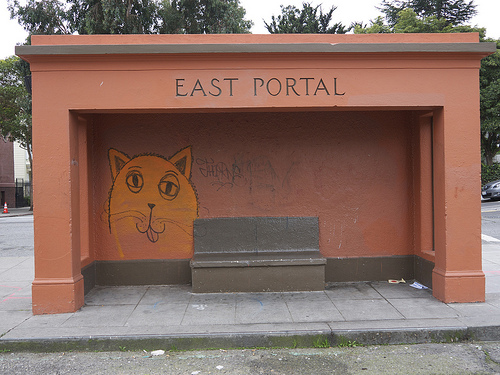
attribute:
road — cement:
[2, 335, 499, 372]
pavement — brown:
[0, 218, 498, 340]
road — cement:
[1, 340, 499, 373]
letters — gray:
[149, 69, 241, 110]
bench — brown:
[165, 210, 352, 297]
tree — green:
[13, 0, 248, 32]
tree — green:
[257, 0, 345, 30]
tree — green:
[380, 1, 482, 31]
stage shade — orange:
[30, 32, 485, 314]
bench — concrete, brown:
[187, 213, 332, 293]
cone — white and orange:
[173, 146, 198, 175]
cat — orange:
[107, 140, 205, 266]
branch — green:
[0, 41, 45, 158]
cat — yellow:
[96, 146, 200, 260]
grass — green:
[266, 321, 384, 371]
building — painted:
[17, 31, 493, 313]